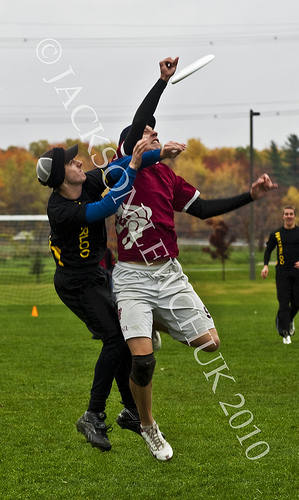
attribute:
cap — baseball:
[35, 136, 91, 192]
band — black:
[47, 140, 66, 198]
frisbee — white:
[162, 40, 263, 109]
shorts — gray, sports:
[108, 258, 218, 344]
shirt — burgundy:
[105, 153, 203, 268]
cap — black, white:
[34, 141, 79, 186]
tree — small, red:
[201, 218, 239, 280]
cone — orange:
[29, 304, 39, 317]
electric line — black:
[1, 111, 249, 115]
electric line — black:
[1, 113, 249, 118]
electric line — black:
[1, 115, 251, 125]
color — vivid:
[108, 139, 196, 262]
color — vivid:
[111, 258, 217, 339]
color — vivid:
[78, 223, 91, 257]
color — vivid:
[45, 232, 64, 266]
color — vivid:
[30, 301, 39, 316]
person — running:
[259, 204, 289, 344]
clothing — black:
[261, 224, 289, 335]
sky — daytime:
[7, 11, 297, 149]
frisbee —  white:
[168, 51, 216, 85]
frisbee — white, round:
[166, 50, 213, 90]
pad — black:
[126, 346, 165, 404]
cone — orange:
[26, 302, 46, 323]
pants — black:
[45, 259, 128, 345]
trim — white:
[180, 185, 201, 211]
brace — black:
[122, 343, 156, 396]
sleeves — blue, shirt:
[82, 146, 161, 225]